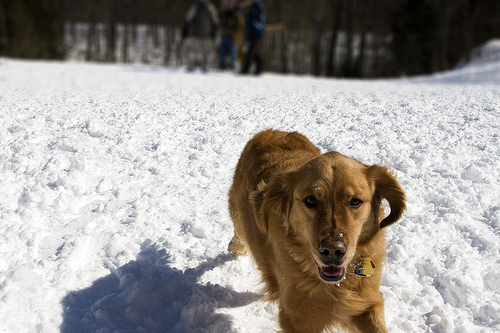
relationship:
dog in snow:
[227, 126, 407, 331] [3, 57, 500, 332]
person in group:
[180, 0, 223, 71] [174, 1, 271, 78]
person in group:
[212, 2, 243, 73] [174, 1, 271, 78]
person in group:
[239, 1, 269, 77] [174, 1, 271, 78]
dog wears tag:
[227, 126, 407, 331] [355, 254, 379, 278]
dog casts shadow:
[227, 126, 407, 331] [59, 236, 264, 331]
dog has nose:
[227, 126, 407, 331] [315, 228, 349, 259]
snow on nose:
[0, 57, 500, 331] [315, 228, 349, 259]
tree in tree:
[0, 1, 500, 77] [0, 1, 500, 77]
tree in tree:
[356, 1, 373, 77] [0, 1, 500, 77]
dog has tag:
[227, 126, 407, 331] [355, 254, 379, 278]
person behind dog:
[180, 0, 223, 71] [227, 126, 407, 331]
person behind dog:
[212, 2, 243, 73] [227, 126, 407, 331]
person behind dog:
[239, 1, 269, 77] [227, 126, 407, 331]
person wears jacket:
[239, 1, 269, 77] [242, 2, 268, 44]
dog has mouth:
[227, 126, 407, 331] [312, 252, 353, 287]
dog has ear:
[227, 126, 407, 331] [246, 167, 295, 236]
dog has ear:
[227, 126, 407, 331] [367, 160, 408, 228]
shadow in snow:
[59, 236, 264, 331] [3, 57, 500, 332]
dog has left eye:
[227, 126, 407, 331] [350, 195, 365, 211]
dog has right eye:
[227, 126, 407, 331] [301, 194, 319, 210]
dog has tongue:
[227, 126, 407, 331] [319, 266, 344, 280]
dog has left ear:
[227, 126, 407, 331] [367, 160, 408, 228]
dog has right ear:
[227, 126, 407, 331] [246, 167, 295, 236]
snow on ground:
[3, 57, 500, 332] [0, 50, 499, 332]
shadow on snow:
[59, 236, 264, 331] [3, 57, 500, 332]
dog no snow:
[227, 126, 407, 331] [3, 57, 500, 332]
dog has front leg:
[227, 126, 407, 331] [351, 303, 389, 331]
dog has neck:
[227, 126, 407, 331] [279, 195, 380, 288]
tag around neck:
[355, 254, 379, 278] [279, 195, 380, 288]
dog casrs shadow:
[227, 126, 407, 331] [59, 236, 264, 331]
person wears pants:
[239, 1, 269, 77] [240, 38, 265, 75]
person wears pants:
[212, 2, 243, 73] [215, 33, 238, 71]